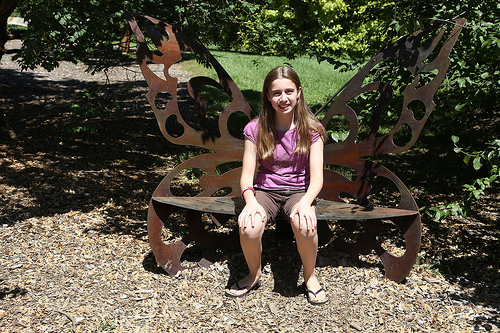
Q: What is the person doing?
A: Sitting.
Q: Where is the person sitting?
A: On a bench.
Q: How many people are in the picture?
A: One.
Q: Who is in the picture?
A: A girl.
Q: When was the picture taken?
A: Daytime.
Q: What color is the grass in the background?
A: Green.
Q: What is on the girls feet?
A: Sandals.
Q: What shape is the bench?
A: A butterfly.